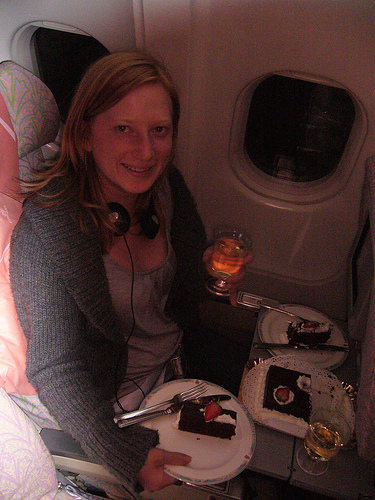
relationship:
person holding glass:
[8, 51, 255, 500] [204, 226, 254, 296]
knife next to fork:
[117, 392, 232, 426] [112, 380, 210, 423]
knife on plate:
[117, 392, 232, 426] [144, 377, 258, 490]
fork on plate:
[112, 380, 210, 423] [144, 377, 258, 490]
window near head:
[224, 66, 370, 207] [85, 56, 178, 203]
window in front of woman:
[237, 69, 357, 190] [5, 43, 258, 460]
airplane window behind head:
[29, 27, 109, 125] [63, 50, 183, 194]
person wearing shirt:
[8, 51, 255, 500] [89, 173, 185, 403]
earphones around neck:
[94, 195, 163, 244] [93, 178, 141, 204]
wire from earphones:
[117, 235, 138, 343] [99, 198, 134, 239]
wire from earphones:
[117, 235, 138, 343] [131, 206, 166, 238]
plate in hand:
[130, 378, 259, 483] [130, 439, 192, 482]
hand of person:
[130, 439, 192, 482] [8, 51, 255, 500]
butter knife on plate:
[117, 388, 231, 427] [144, 377, 258, 490]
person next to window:
[8, 51, 255, 500] [237, 69, 357, 190]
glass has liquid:
[204, 226, 254, 296] [213, 237, 245, 272]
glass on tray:
[295, 406, 348, 477] [235, 289, 360, 499]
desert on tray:
[278, 310, 331, 351] [240, 305, 365, 493]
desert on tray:
[256, 360, 316, 431] [240, 305, 365, 493]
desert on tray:
[172, 400, 238, 442] [240, 305, 365, 493]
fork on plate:
[113, 380, 210, 424] [130, 378, 259, 483]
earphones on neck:
[104, 200, 161, 414] [96, 169, 151, 208]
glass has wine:
[205, 227, 252, 295] [211, 237, 240, 274]